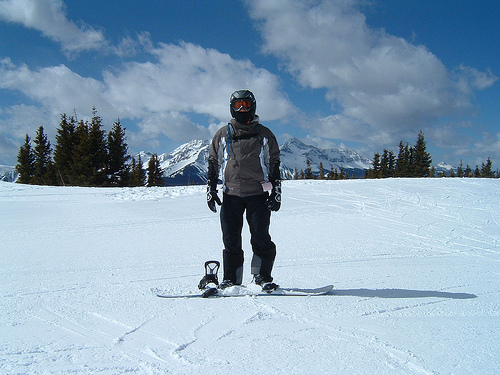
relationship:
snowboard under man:
[150, 282, 335, 299] [207, 89, 282, 293]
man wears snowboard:
[207, 89, 282, 293] [150, 282, 335, 299]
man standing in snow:
[207, 89, 282, 293] [2, 179, 499, 371]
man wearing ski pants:
[207, 89, 282, 293] [219, 193, 274, 284]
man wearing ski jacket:
[207, 89, 282, 293] [206, 117, 286, 195]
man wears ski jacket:
[207, 89, 282, 293] [206, 117, 286, 195]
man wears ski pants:
[207, 89, 282, 293] [219, 193, 274, 284]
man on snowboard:
[207, 89, 282, 293] [150, 282, 335, 299]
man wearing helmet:
[207, 89, 282, 293] [229, 90, 258, 124]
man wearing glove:
[207, 89, 282, 293] [205, 187, 221, 213]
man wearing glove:
[207, 89, 282, 293] [267, 186, 282, 211]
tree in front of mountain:
[105, 119, 130, 185] [122, 134, 419, 182]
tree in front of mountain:
[75, 120, 96, 187] [122, 134, 419, 182]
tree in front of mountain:
[54, 112, 75, 188] [122, 134, 419, 182]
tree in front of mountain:
[32, 124, 54, 185] [122, 134, 419, 182]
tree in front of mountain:
[16, 133, 36, 180] [122, 134, 419, 182]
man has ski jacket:
[207, 89, 282, 293] [206, 117, 286, 195]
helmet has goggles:
[229, 90, 258, 124] [229, 95, 255, 112]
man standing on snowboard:
[207, 89, 282, 293] [150, 282, 335, 299]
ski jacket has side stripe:
[206, 117, 286, 195] [218, 134, 230, 192]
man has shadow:
[207, 89, 282, 293] [284, 282, 478, 304]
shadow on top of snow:
[284, 282, 478, 304] [2, 179, 499, 371]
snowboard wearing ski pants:
[150, 282, 335, 299] [219, 193, 274, 284]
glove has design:
[205, 187, 221, 213] [204, 186, 211, 204]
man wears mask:
[207, 89, 282, 293] [231, 109, 258, 123]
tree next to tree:
[16, 133, 36, 180] [32, 124, 54, 185]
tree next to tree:
[54, 112, 75, 188] [75, 120, 96, 187]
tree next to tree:
[75, 120, 96, 187] [105, 119, 130, 185]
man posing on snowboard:
[207, 89, 282, 293] [150, 282, 335, 299]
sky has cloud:
[2, 3, 498, 166] [2, 40, 298, 129]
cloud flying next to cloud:
[250, 3, 493, 119] [299, 109, 375, 146]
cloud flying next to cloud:
[2, 40, 298, 129] [0, 2, 112, 59]